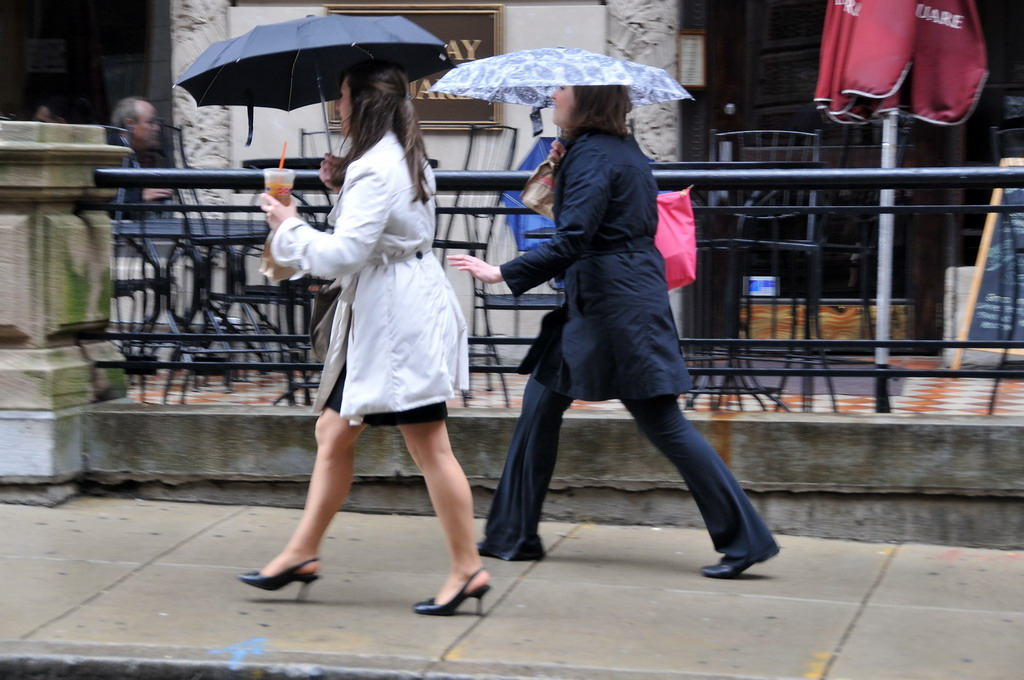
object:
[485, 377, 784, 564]
pant suit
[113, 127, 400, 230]
tables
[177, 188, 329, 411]
chairs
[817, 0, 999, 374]
parasol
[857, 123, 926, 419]
stand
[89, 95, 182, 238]
man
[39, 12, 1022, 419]
eatery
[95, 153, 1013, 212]
railing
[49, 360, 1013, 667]
sidewalk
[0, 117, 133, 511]
pillar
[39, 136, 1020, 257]
railing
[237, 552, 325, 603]
shoe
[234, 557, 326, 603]
foot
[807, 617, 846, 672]
line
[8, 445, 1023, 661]
ground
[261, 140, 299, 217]
drink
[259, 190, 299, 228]
hand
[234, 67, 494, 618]
girl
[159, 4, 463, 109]
umbrella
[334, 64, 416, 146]
head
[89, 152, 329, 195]
post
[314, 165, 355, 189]
handle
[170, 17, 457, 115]
object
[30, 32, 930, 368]
distance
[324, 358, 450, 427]
black shirt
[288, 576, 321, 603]
high heel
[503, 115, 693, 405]
jacket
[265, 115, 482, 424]
whit coat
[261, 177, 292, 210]
iced coffee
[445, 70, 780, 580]
girl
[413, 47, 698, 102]
blue umbrella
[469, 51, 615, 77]
floral design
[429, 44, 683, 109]
canopy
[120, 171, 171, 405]
safety rail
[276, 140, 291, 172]
red straw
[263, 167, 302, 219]
coffee cup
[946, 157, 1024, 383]
chalkboard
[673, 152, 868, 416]
metaltable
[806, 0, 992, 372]
red umbrella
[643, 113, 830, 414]
chairs